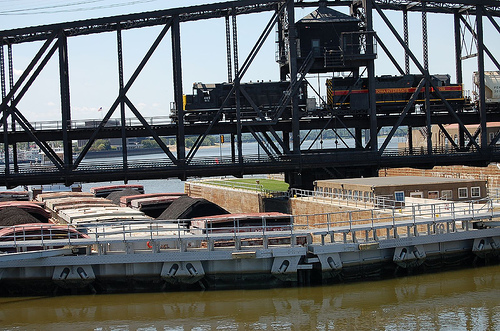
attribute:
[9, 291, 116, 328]
water — brown, green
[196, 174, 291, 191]
grass — green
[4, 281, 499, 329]
water — green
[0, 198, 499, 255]
railing — gray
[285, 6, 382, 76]
building — small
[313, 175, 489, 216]
building — small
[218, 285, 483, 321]
water — calm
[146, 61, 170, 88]
sky — overcast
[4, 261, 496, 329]
water — calm, brown, murky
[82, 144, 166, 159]
ship — large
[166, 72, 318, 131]
engine — lead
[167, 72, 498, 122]
train — black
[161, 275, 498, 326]
water surface — reflecting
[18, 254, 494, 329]
water — reflecting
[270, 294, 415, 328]
water — brown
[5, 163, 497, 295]
ferry — big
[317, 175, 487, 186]
roof — flat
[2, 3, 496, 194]
bridge — black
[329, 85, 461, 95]
stripe — orange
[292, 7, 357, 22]
roof — pointed